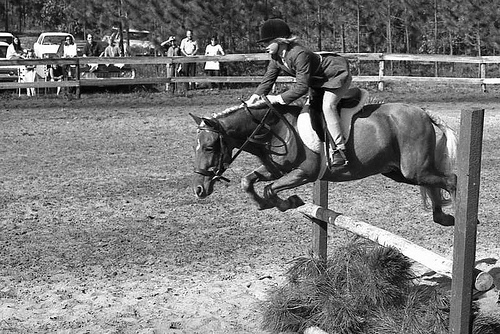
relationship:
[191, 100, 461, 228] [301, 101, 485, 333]
horse jumping over fence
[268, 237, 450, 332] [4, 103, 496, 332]
patch of grass on top of dirt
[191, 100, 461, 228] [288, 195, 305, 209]
horse has hoof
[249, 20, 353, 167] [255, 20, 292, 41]
rider wearing helmet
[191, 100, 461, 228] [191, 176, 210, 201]
horse has nose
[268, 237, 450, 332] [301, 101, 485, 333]
patch of grass under fence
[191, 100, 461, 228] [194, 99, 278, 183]
horse wearing reign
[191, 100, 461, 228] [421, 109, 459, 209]
horse has tail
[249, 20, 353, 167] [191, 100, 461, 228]
rider riding horse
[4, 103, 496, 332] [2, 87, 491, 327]
dirt covers field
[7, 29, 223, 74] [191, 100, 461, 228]
people are watching horse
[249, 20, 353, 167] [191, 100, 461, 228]
rider jumping with horse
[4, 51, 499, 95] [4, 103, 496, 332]
fence surrounding dirt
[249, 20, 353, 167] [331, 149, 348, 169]
rider wearing boot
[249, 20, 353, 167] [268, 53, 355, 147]
rider wearing riding outfit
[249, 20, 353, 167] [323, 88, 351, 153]
rider wearing pants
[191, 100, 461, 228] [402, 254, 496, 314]
horse casting shadow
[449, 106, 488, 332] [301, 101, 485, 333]
post attached to fence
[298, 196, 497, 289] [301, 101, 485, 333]
rail attached to fence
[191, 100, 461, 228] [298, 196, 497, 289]
horse jumping over rail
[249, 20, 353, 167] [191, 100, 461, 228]
rider on top of horse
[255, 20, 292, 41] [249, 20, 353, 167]
helmet on top of rider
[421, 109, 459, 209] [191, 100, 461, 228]
tail on backside of horse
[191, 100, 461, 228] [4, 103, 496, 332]
horse galloping over dirt